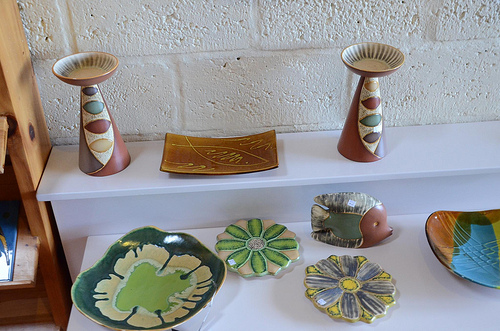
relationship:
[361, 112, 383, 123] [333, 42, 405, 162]
design on holder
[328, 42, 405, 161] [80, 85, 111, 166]
holder has design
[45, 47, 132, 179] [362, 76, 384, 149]
holder has design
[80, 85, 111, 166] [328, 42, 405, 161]
design in front of holder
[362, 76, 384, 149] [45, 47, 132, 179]
design in front of holder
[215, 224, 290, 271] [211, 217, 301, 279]
pottery has pottery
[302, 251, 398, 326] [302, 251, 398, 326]
pottery has pottery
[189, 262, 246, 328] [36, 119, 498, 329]
shadow on shelf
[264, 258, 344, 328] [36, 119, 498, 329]
shadow on shelf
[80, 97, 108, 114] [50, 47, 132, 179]
design on holder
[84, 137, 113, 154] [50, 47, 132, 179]
oval on holder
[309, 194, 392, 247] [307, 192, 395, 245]
craft made fish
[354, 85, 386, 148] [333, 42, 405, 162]
design on holder